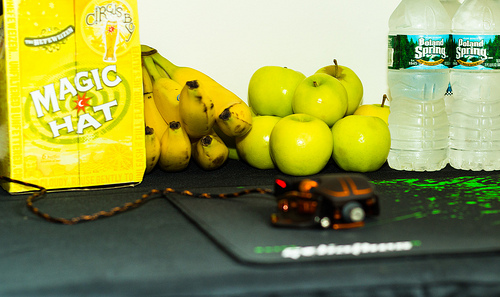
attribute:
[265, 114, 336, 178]
apple — medium sized, green, yellow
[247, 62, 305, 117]
apple — medium sized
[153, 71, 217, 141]
banana — yellow, ripe, aging, pointier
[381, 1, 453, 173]
bottle — clear, cold, water filled, icy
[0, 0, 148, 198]
carton — yellow, beer filled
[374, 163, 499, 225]
splatter — neon, green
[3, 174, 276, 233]
string — orange, black, brown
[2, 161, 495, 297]
table — gray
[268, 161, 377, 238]
toy — orange, brown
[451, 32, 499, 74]
label — poland spring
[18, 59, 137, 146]
logo — swirly looking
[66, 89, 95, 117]
star — red